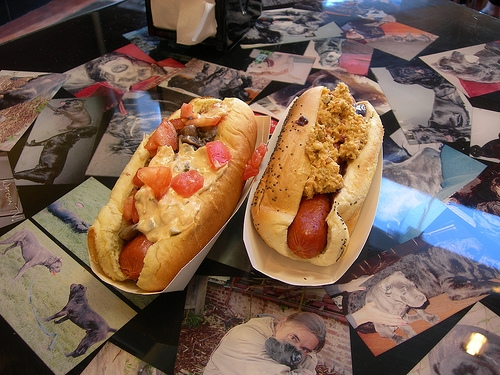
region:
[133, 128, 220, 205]
Tomatoe on a hotdog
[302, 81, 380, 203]
Sauce on a hotdog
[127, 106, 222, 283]
Orange sauce on a hot dog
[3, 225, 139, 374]
Two dogs in a photo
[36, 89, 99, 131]
Photo of a brown dog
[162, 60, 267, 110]
Black dog in a photo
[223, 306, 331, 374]
Person holding a dog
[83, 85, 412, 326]
Two hot dogs on a table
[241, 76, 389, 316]
Hot dog on a table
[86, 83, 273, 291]
Hot dog in a tray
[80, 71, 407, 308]
two hot dogs on small plates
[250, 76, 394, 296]
a hot dog in a paper plate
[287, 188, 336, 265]
hot dog is red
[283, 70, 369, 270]
hot dog is cover with a cream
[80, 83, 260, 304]
hot dog is cover with mayonnaise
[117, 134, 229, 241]
mayonnaise over the hot dog is yellow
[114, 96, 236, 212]
pieces of tomato over mayonnaise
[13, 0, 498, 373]
pictures are spread on a table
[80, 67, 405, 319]
two hot dogs in the middle of pictures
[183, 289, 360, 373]
picture of a woman with a dog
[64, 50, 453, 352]
Two hot dogs on photographs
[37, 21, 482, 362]
Food and photographs on the table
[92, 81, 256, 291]
Hot dog with sauce and tomatoes.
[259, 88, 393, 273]
Hot dog with tuna or something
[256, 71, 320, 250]
Poppy seed roll and hot dog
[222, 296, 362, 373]
Photo of man hugging dog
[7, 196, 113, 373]
Photo of two dogs watching each other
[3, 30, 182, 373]
Lots of pictures of pets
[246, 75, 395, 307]
Hot dog in a cardboard container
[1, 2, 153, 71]
Another table to the left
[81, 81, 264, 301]
A hotdog on a bun.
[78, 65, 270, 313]
A hotdog in a container.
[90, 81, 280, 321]
The container is white.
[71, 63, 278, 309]
The container is cardboard.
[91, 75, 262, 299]
Diced tomatoes on a hotdog.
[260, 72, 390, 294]
The bun is seeded.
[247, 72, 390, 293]
The hotdog has been cooked.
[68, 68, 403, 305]
Two hotdogs side by side.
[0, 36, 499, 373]
Hotdog on top of photographs.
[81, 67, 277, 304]
Nacho cheese on a hotdog.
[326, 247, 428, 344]
A dog is visible.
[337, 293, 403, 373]
A dog is visible.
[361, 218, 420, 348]
A dog is visible.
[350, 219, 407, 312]
A dog is visible.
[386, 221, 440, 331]
A dog is visible.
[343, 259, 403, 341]
A dog is visible.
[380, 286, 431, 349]
A dog is visible.